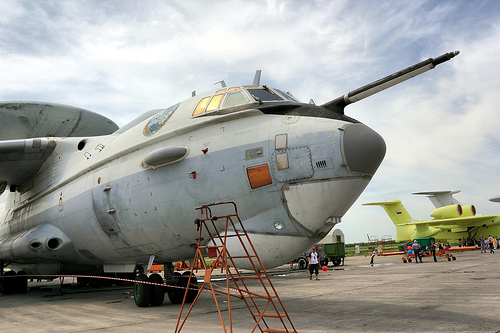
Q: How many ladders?
A: 1.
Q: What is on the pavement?
A: Plane.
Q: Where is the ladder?
A: In front of the plane.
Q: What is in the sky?
A: Clouds.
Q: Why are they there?
A: Preparing them.